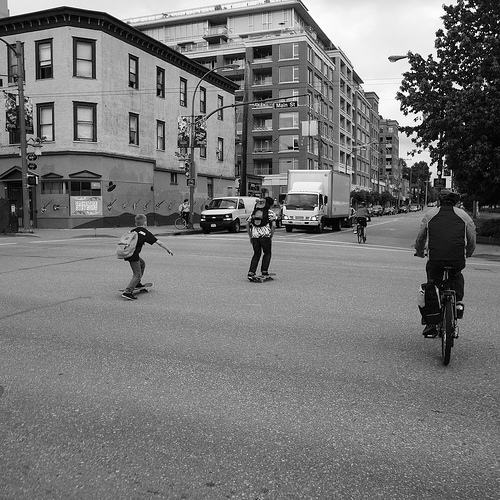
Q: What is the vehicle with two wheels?
A: Bicycle.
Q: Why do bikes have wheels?
A: To roll.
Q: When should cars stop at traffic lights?
A: When red.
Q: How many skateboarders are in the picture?
A: Two.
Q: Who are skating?
A: Skateboarders.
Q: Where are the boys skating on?
A: Street.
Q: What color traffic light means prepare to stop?
A: Yellow.